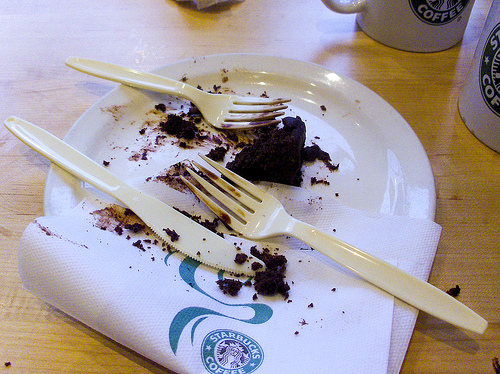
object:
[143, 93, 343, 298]
food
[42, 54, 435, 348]
plate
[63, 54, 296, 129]
forks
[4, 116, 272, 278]
knife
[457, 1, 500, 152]
mug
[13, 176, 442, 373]
napkin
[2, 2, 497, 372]
table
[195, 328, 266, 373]
logo